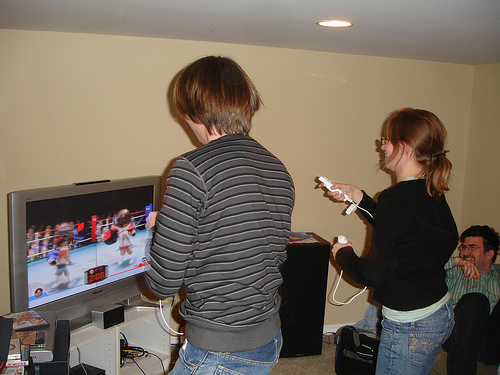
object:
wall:
[1, 27, 497, 337]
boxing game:
[26, 185, 153, 311]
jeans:
[373, 294, 456, 375]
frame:
[8, 195, 28, 312]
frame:
[6, 175, 166, 202]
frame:
[13, 271, 164, 336]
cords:
[118, 332, 165, 375]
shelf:
[116, 307, 171, 375]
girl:
[318, 108, 458, 375]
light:
[317, 18, 354, 28]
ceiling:
[1, 1, 498, 68]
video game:
[35, 212, 152, 265]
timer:
[84, 264, 109, 285]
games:
[3, 309, 48, 351]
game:
[316, 18, 356, 29]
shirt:
[144, 135, 296, 353]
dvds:
[0, 310, 55, 375]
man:
[442, 224, 499, 375]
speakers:
[278, 232, 331, 358]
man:
[143, 52, 297, 375]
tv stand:
[28, 299, 172, 375]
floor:
[269, 317, 499, 374]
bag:
[332, 325, 379, 374]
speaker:
[91, 304, 125, 330]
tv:
[6, 175, 163, 323]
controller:
[317, 175, 352, 202]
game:
[8, 175, 165, 337]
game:
[28, 187, 164, 302]